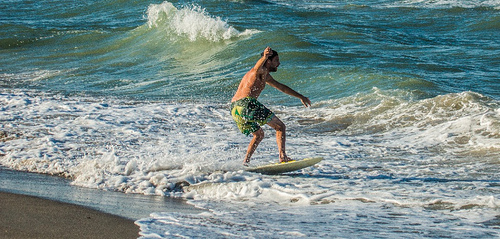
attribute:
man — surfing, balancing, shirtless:
[229, 46, 310, 167]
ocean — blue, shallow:
[0, 0, 499, 237]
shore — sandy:
[1, 166, 208, 239]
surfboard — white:
[247, 155, 324, 173]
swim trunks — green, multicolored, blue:
[229, 97, 273, 135]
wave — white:
[105, 2, 329, 87]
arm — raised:
[252, 47, 272, 78]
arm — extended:
[266, 74, 311, 107]